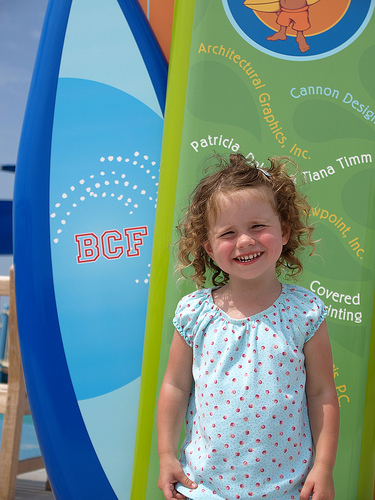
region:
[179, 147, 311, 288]
Curly hair on a little girl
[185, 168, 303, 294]
A little girl's smiling face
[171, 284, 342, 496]
A pale blue shirt with pink dots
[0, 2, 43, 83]
A pale blue sky peeking from behind a surf board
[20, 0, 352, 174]
Surfboards leaning on each other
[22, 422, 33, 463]
Shining water in the background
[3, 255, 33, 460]
A wooden stand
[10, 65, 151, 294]
A light blue surfboard with medium blue trim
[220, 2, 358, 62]
A character printed on a surf board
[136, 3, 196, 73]
An orange surfboard behind two others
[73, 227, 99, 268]
a letter is written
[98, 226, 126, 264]
a letter is written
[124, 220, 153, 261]
a letter is written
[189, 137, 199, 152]
a letter is written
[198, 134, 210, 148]
a letter is written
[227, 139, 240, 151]
a letter is written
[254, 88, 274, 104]
a letter is written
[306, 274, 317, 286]
a letter is written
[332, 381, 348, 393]
a letter is written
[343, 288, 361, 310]
a letter is written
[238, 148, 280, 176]
white ribbon in girl's hair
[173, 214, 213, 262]
red curls in girl's hair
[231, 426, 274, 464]
red spot on blue shirt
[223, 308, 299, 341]
collar on blue shirt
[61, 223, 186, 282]
red words on board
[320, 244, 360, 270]
green background on the board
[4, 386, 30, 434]
edge of brown chair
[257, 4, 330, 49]
orange shorts on the board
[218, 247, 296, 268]
wide grin on girl's face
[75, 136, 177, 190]
small white spots on the board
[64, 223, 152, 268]
BCF on a surfboard.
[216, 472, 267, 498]
Red flowers on the shirt.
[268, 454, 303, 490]
The shirt is mostly blue.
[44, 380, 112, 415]
The surfboard is blue.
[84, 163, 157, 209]
White dots on the surfboard.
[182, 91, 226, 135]
The surfboard is green.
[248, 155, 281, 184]
Blue barrette in the girls hair.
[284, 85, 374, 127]
Canon Design on the surfboard.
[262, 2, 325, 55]
Cartoon drawing in orange shorts on the surfboard.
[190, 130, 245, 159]
Patricia on the surfboard.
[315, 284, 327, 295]
a letter is written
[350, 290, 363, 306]
a letter is written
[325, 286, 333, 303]
a letter is written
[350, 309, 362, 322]
a letter is written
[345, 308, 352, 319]
a letter is written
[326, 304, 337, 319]
a letter is written